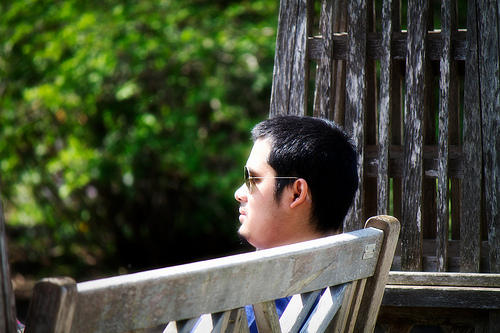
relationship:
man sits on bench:
[233, 110, 363, 332] [23, 212, 403, 323]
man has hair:
[233, 110, 363, 332] [246, 113, 360, 237]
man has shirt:
[233, 110, 363, 332] [242, 286, 329, 332]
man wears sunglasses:
[233, 110, 363, 332] [242, 162, 312, 204]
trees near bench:
[1, 0, 473, 290] [23, 212, 403, 323]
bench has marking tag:
[23, 212, 403, 323] [359, 243, 378, 261]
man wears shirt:
[233, 110, 363, 332] [242, 286, 329, 332]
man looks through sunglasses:
[233, 110, 363, 332] [242, 162, 312, 204]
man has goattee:
[233, 110, 363, 332] [235, 226, 252, 242]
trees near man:
[1, 0, 473, 290] [233, 110, 363, 332]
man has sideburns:
[233, 110, 363, 332] [274, 182, 294, 209]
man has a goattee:
[233, 110, 363, 332] [235, 226, 252, 242]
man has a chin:
[233, 110, 363, 332] [237, 223, 256, 248]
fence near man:
[265, 1, 490, 317] [233, 110, 363, 332]